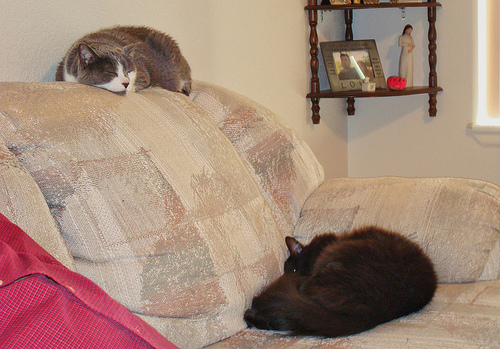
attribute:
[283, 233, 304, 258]
ear — black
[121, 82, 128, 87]
nose — black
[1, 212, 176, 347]
material — pink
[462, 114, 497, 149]
window sill — white 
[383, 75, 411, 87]
object — red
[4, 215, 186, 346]
blanket — red 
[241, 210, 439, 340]
cat — black 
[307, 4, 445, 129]
wall shelf — wooden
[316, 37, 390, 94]
frame — gray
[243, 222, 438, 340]
black cat — curled up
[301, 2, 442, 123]
shelf — brown 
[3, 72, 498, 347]
sofa — gray, cream 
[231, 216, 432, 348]
cat — black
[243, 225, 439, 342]
cat — curled 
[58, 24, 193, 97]
cat — gray, white 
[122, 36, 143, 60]
ear — gray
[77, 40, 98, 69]
ear — gray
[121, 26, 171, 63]
fur — gray